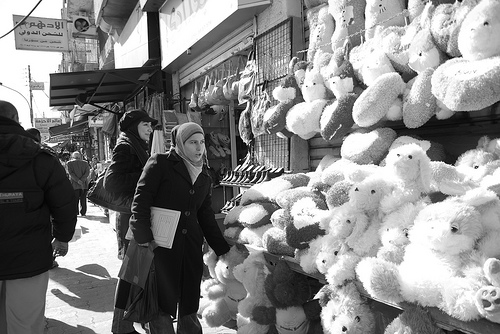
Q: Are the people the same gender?
A: No, they are both male and female.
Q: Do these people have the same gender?
A: No, they are both male and female.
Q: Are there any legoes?
A: No, there are no legoes.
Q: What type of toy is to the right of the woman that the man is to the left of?
A: The toy is a stuffed animal.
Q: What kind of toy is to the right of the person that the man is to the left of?
A: The toy is a stuffed animal.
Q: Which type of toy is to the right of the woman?
A: The toy is a stuffed animal.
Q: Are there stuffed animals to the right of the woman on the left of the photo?
A: Yes, there is a stuffed animal to the right of the woman.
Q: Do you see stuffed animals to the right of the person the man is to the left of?
A: Yes, there is a stuffed animal to the right of the woman.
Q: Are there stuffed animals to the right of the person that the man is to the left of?
A: Yes, there is a stuffed animal to the right of the woman.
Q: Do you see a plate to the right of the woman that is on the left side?
A: No, there is a stuffed animal to the right of the woman.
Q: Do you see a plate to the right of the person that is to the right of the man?
A: No, there is a stuffed animal to the right of the woman.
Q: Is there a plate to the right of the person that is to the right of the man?
A: No, there is a stuffed animal to the right of the woman.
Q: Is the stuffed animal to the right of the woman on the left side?
A: Yes, the stuffed animal is to the right of the woman.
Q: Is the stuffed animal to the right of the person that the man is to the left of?
A: Yes, the stuffed animal is to the right of the woman.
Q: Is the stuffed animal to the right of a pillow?
A: No, the stuffed animal is to the right of the woman.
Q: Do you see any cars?
A: No, there are no cars.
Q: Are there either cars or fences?
A: No, there are no cars or fences.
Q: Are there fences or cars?
A: No, there are no cars or fences.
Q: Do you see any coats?
A: Yes, there is a coat.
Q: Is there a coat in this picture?
A: Yes, there is a coat.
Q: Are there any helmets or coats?
A: Yes, there is a coat.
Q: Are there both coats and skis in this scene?
A: No, there is a coat but no skis.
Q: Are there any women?
A: Yes, there is a woman.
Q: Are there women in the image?
A: Yes, there is a woman.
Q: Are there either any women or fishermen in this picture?
A: Yes, there is a woman.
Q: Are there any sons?
A: No, there are no sons.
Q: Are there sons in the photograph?
A: No, there are no sons.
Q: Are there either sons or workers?
A: No, there are no sons or workers.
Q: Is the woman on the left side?
A: Yes, the woman is on the left of the image.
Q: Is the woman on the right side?
A: No, the woman is on the left of the image.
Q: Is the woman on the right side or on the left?
A: The woman is on the left of the image.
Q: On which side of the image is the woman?
A: The woman is on the left of the image.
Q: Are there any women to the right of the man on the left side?
A: Yes, there is a woman to the right of the man.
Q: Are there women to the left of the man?
A: No, the woman is to the right of the man.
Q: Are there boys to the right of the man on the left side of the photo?
A: No, there is a woman to the right of the man.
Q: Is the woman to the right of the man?
A: Yes, the woman is to the right of the man.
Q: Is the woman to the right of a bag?
A: No, the woman is to the right of the man.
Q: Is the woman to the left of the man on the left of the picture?
A: No, the woman is to the right of the man.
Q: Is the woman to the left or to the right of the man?
A: The woman is to the right of the man.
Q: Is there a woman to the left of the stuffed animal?
A: Yes, there is a woman to the left of the stuffed animal.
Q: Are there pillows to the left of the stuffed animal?
A: No, there is a woman to the left of the stuffed animal.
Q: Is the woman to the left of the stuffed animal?
A: Yes, the woman is to the left of the stuffed animal.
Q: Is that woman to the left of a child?
A: No, the woman is to the left of the stuffed animal.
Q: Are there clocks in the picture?
A: No, there are no clocks.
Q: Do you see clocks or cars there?
A: No, there are no clocks or cars.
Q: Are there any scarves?
A: Yes, there is a scarf.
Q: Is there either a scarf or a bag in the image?
A: Yes, there is a scarf.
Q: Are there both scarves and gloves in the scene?
A: No, there is a scarf but no gloves.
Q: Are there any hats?
A: Yes, there is a hat.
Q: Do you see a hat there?
A: Yes, there is a hat.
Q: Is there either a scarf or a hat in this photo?
A: Yes, there is a hat.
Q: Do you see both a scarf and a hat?
A: Yes, there are both a hat and a scarf.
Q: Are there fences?
A: No, there are no fences.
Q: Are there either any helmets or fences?
A: No, there are no fences or helmets.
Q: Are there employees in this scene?
A: No, there are no employees.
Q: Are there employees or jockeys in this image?
A: No, there are no employees or jockeys.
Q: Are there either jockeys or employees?
A: No, there are no employees or jockeys.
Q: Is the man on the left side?
A: Yes, the man is on the left of the image.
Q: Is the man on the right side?
A: No, the man is on the left of the image.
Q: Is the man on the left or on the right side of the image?
A: The man is on the left of the image.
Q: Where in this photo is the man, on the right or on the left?
A: The man is on the left of the image.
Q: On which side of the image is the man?
A: The man is on the left of the image.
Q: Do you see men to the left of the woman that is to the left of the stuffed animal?
A: Yes, there is a man to the left of the woman.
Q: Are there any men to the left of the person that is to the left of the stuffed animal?
A: Yes, there is a man to the left of the woman.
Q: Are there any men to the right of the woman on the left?
A: No, the man is to the left of the woman.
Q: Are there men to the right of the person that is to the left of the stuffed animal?
A: No, the man is to the left of the woman.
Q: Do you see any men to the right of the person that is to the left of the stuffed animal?
A: No, the man is to the left of the woman.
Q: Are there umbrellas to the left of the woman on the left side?
A: No, there is a man to the left of the woman.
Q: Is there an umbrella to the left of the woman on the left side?
A: No, there is a man to the left of the woman.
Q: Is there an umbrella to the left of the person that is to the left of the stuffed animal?
A: No, there is a man to the left of the woman.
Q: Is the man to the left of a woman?
A: Yes, the man is to the left of a woman.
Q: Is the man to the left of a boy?
A: No, the man is to the left of a woman.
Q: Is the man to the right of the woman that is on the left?
A: No, the man is to the left of the woman.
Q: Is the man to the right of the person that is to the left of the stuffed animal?
A: No, the man is to the left of the woman.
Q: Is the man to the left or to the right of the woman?
A: The man is to the left of the woman.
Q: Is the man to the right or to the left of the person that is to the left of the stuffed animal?
A: The man is to the left of the woman.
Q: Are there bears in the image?
A: Yes, there is a bear.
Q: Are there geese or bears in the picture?
A: Yes, there is a bear.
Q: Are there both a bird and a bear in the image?
A: No, there is a bear but no birds.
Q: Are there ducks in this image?
A: No, there are no ducks.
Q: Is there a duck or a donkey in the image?
A: No, there are no ducks or donkeys.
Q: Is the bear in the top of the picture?
A: No, the bear is in the bottom of the image.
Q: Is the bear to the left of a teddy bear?
A: Yes, the bear is to the left of a teddy bear.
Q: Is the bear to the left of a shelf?
A: No, the bear is to the left of a teddy bear.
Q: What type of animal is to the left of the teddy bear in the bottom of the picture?
A: The animal is a bear.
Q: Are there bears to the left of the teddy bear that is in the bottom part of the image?
A: Yes, there is a bear to the left of the teddy bear.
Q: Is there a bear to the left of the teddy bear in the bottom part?
A: Yes, there is a bear to the left of the teddy bear.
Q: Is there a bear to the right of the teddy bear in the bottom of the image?
A: No, the bear is to the left of the teddy bear.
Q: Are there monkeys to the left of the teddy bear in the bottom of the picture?
A: No, there is a bear to the left of the teddy bear.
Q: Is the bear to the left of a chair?
A: No, the bear is to the left of a teddy bear.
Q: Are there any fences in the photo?
A: No, there are no fences.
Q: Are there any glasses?
A: No, there are no glasses.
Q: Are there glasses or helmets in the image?
A: No, there are no glasses or helmets.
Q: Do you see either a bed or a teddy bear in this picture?
A: Yes, there is a teddy bear.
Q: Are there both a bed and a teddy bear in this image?
A: No, there is a teddy bear but no beds.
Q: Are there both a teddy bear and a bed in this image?
A: No, there is a teddy bear but no beds.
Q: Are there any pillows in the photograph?
A: No, there are no pillows.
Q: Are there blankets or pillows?
A: No, there are no pillows or blankets.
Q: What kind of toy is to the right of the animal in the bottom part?
A: The toy is a teddy bear.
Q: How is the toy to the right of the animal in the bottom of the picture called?
A: The toy is a teddy bear.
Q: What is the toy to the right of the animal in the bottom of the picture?
A: The toy is a teddy bear.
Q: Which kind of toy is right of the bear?
A: The toy is a teddy bear.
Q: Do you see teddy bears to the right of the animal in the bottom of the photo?
A: Yes, there is a teddy bear to the right of the bear.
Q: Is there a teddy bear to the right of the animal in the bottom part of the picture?
A: Yes, there is a teddy bear to the right of the bear.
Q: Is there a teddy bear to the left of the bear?
A: No, the teddy bear is to the right of the bear.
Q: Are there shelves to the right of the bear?
A: No, there is a teddy bear to the right of the bear.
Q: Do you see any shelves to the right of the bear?
A: No, there is a teddy bear to the right of the bear.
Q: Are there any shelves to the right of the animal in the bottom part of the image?
A: No, there is a teddy bear to the right of the bear.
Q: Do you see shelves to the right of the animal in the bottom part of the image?
A: No, there is a teddy bear to the right of the bear.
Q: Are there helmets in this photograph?
A: No, there are no helmets.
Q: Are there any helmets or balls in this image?
A: No, there are no helmets or balls.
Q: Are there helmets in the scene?
A: No, there are no helmets.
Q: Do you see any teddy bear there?
A: Yes, there is a teddy bear.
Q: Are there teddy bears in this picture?
A: Yes, there is a teddy bear.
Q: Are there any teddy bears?
A: Yes, there is a teddy bear.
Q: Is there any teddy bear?
A: Yes, there is a teddy bear.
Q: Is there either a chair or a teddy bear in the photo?
A: Yes, there is a teddy bear.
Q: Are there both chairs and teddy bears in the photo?
A: No, there is a teddy bear but no chairs.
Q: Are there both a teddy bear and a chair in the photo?
A: No, there is a teddy bear but no chairs.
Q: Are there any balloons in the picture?
A: No, there are no balloons.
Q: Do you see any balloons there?
A: No, there are no balloons.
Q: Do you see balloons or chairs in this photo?
A: No, there are no balloons or chairs.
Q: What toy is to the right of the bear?
A: The toy is a teddy bear.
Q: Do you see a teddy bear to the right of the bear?
A: Yes, there is a teddy bear to the right of the bear.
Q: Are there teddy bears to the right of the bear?
A: Yes, there is a teddy bear to the right of the bear.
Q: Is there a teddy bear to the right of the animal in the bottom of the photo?
A: Yes, there is a teddy bear to the right of the bear.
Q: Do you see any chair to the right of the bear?
A: No, there is a teddy bear to the right of the bear.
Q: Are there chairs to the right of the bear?
A: No, there is a teddy bear to the right of the bear.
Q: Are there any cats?
A: No, there are no cats.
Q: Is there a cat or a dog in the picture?
A: No, there are no cats or dogs.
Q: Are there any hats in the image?
A: Yes, there is a hat.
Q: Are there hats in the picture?
A: Yes, there is a hat.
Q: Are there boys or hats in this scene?
A: Yes, there is a hat.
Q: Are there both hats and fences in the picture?
A: No, there is a hat but no fences.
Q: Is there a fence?
A: No, there are no fences.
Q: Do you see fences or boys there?
A: No, there are no fences or boys.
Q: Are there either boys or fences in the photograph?
A: No, there are no fences or boys.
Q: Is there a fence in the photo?
A: No, there are no fences.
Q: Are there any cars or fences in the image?
A: No, there are no fences or cars.